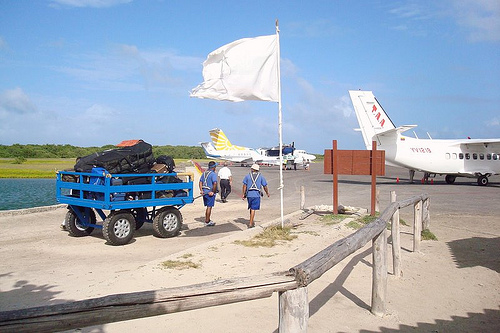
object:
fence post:
[371, 223, 390, 320]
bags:
[77, 139, 155, 170]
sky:
[2, 2, 196, 138]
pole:
[276, 25, 283, 228]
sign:
[323, 140, 385, 218]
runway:
[197, 157, 498, 209]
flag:
[189, 33, 285, 103]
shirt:
[219, 167, 231, 180]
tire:
[101, 212, 137, 244]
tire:
[64, 214, 92, 235]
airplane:
[353, 87, 500, 176]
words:
[366, 101, 389, 131]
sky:
[282, 0, 500, 90]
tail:
[347, 87, 412, 146]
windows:
[454, 151, 465, 162]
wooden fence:
[294, 220, 386, 285]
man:
[193, 160, 221, 227]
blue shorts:
[243, 200, 263, 215]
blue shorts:
[198, 193, 216, 208]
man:
[217, 160, 232, 202]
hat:
[250, 162, 260, 171]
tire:
[150, 205, 182, 237]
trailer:
[56, 170, 193, 245]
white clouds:
[0, 0, 188, 141]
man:
[242, 164, 268, 229]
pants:
[217, 181, 231, 205]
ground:
[2, 157, 500, 333]